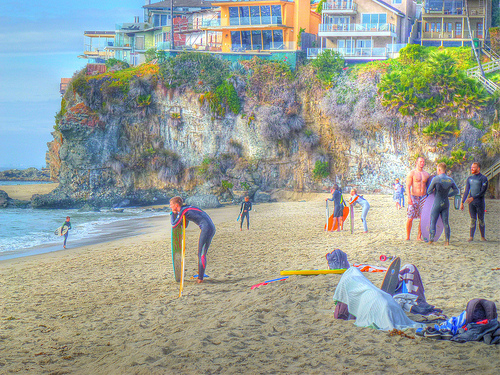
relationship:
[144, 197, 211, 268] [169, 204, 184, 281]
man with surfboard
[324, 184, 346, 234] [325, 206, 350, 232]
person standing next to surfboard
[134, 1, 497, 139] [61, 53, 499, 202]
yellow house on cliff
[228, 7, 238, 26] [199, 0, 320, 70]
window on house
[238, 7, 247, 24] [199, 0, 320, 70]
window on house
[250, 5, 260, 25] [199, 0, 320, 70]
window on house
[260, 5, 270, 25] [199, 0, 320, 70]
window on house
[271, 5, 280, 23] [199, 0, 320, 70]
window on house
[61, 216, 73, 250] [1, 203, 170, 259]
man coming out of water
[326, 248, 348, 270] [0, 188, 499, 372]
bag on beach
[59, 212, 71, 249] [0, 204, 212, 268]
surfer getting out of sea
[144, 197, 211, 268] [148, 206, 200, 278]
man with surfboard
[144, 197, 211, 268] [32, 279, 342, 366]
man standing on sand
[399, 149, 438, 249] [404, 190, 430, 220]
man wearing trunks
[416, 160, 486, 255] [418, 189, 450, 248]
man holding board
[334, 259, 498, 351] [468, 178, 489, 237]
man wearing wetsuit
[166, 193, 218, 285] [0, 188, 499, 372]
person on beach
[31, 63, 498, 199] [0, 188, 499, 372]
cliff on beach